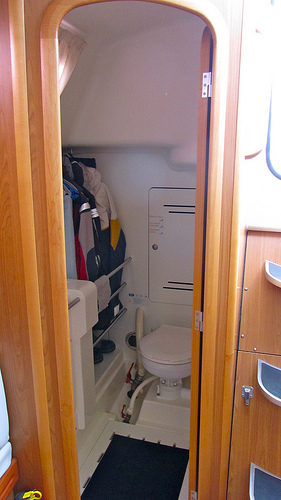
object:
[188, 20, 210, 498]
door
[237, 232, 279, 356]
door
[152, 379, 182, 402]
bottom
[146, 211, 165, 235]
label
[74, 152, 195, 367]
wall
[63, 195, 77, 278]
sleeves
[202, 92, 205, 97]
screws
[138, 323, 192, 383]
toilet bowl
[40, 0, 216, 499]
door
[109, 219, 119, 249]
design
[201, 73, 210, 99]
hinge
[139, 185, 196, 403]
toilet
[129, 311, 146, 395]
pipe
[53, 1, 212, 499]
bathroom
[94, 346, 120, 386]
shelf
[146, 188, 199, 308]
door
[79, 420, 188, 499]
floor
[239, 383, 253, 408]
handle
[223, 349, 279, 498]
door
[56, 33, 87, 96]
curtain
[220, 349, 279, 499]
cabinet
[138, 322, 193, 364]
toilet seat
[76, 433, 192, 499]
mat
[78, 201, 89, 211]
stripes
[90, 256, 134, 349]
handrails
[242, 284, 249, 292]
button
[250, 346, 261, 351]
button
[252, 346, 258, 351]
button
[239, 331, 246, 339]
button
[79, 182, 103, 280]
clothing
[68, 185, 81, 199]
clothing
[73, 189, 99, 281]
clothing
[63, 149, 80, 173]
rack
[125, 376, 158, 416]
pipe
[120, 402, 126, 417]
valve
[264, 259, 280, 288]
storage shelf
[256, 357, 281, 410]
storage shelf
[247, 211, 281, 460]
storage shelf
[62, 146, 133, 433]
closet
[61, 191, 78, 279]
clothes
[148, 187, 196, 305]
access panel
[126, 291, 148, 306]
sticker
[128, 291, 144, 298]
lettering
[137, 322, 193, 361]
lid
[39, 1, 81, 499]
door frame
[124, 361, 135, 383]
valve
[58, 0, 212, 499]
shower area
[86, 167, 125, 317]
clothing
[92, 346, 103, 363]
boot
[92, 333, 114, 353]
boot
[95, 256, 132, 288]
bar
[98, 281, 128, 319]
bar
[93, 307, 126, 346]
bar